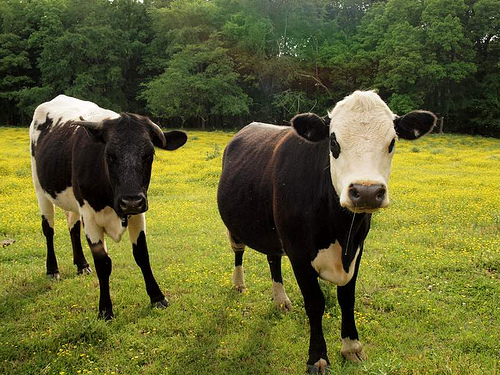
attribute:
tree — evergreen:
[5, 5, 115, 101]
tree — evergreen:
[153, 5, 249, 120]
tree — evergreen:
[362, 5, 491, 104]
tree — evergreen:
[248, 4, 362, 106]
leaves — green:
[382, 25, 423, 65]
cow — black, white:
[184, 70, 440, 372]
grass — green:
[165, 220, 229, 367]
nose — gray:
[338, 175, 398, 218]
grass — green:
[1, 122, 498, 374]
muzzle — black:
[103, 196, 160, 226]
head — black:
[76, 109, 181, 229]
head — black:
[82, 117, 175, 223]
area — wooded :
[2, 5, 497, 132]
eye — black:
[328, 131, 341, 158]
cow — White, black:
[21, 73, 181, 352]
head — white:
[291, 90, 437, 214]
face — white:
[326, 90, 390, 199]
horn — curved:
[140, 111, 185, 151]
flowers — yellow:
[1, 135, 491, 284]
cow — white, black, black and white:
[215, 81, 435, 373]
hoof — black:
[146, 293, 171, 310]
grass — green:
[400, 233, 471, 352]